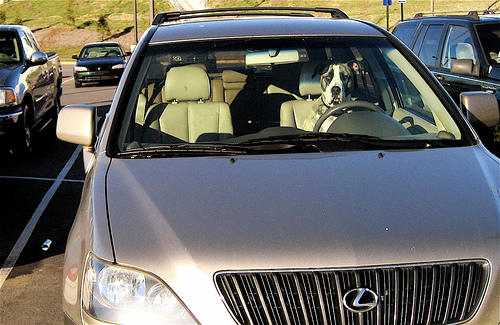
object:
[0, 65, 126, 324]
ground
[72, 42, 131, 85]
car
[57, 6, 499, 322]
vehicle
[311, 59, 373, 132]
dog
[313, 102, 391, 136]
steering wheel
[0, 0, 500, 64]
grass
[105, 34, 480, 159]
windshield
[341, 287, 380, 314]
lexus logo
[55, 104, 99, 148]
side view mirror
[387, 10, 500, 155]
suv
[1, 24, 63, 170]
truck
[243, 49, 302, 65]
rear view mirror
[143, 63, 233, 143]
passenger seat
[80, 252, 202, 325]
headlight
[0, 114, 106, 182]
parking space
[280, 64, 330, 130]
drivers seat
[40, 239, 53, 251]
can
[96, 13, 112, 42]
tree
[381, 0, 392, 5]
sign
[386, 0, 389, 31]
post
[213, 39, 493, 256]
front grille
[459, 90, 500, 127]
side view mirror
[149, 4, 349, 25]
luggage rack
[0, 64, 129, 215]
parking lot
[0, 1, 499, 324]
photo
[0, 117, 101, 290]
line